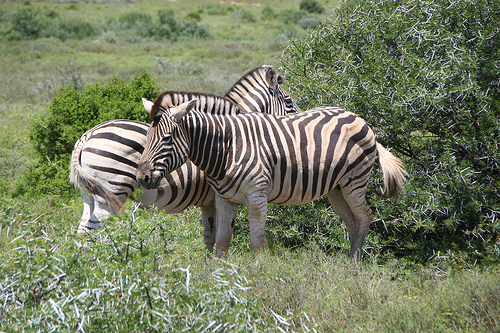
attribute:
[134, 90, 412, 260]
zebra — facing right, facing left, standing, black, white, striped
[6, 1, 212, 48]
bushes — small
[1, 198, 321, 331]
grass — long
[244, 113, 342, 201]
stripes — horizontal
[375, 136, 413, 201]
tail — fluffy, white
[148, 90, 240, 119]
hair — mohawk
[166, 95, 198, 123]
ear — white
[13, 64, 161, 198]
bush — bright green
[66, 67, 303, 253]
zebra — facing right, back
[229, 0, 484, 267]
bushes — large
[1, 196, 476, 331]
grass — rough, wild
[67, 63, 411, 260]
zebras — thorny, napping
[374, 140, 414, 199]
tail — left facing, zebra's, swaying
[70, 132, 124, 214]
tail — right facing, zebra's, close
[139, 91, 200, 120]
ears — zebra's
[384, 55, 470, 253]
bush — green 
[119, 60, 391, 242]
zebra — green , large 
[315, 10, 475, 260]
bush — big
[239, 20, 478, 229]
leaves — dark green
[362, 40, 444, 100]
leaves — green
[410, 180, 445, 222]
leaves — green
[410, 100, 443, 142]
leaves — green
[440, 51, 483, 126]
leaves — green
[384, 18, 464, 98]
leaves — green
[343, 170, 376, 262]
leg — back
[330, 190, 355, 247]
leg — back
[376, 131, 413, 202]
tail — bushy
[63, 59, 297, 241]
zebra — back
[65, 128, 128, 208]
tail — bushy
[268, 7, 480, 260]
bush — large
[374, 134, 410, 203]
tail — swinging, zebra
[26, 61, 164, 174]
bush — small, green, scrub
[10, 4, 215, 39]
bushes — scrub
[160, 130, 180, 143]
eyes — half, closed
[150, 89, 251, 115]
mane — upright, black, white, zebra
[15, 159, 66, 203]
bush — small, green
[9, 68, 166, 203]
bush — small, light green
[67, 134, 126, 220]
tail — large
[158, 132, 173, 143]
eye — black, small